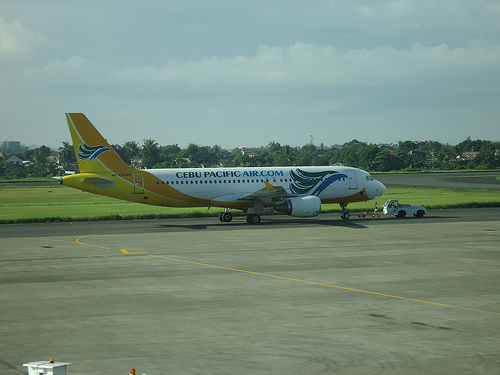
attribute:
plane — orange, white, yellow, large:
[55, 110, 386, 227]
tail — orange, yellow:
[49, 110, 136, 201]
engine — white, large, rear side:
[272, 190, 323, 221]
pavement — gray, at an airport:
[1, 206, 499, 373]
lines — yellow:
[0, 231, 498, 319]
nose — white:
[373, 175, 387, 201]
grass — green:
[0, 171, 499, 221]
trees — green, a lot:
[0, 136, 498, 177]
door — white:
[345, 166, 359, 190]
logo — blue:
[78, 142, 109, 165]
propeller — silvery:
[49, 172, 61, 184]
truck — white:
[384, 199, 428, 221]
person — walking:
[371, 203, 380, 217]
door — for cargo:
[191, 187, 215, 207]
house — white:
[6, 154, 21, 165]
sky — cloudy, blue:
[2, 2, 499, 151]